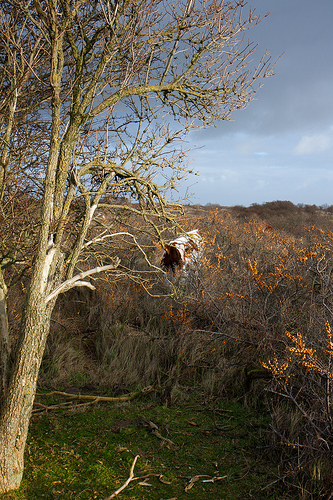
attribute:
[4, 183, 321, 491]
bushes — thick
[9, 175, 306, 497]
bushes — thick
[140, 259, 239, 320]
bushes — thick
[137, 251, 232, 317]
bushes — thick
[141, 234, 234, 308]
bushes — thick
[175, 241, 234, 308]
bushes — thick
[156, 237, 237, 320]
bushes — thick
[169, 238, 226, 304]
bushes — thick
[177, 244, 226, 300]
bushes — thick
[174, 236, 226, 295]
bushes — thick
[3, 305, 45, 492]
bark — brown, green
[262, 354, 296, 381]
leaves — dead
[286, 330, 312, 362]
leaves — orange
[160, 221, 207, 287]
cow — white, brown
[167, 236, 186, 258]
patch — white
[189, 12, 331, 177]
skies — cloudy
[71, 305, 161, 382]
grass — tall, brown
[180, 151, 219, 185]
clouds — white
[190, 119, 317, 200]
sky — blue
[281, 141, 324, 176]
clouds — white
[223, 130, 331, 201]
sky — blue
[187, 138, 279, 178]
sky — blue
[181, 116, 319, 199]
clouds — white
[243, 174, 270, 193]
clouds — white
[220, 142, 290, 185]
sky — blue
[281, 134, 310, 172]
sky — blue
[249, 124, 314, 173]
clouds — white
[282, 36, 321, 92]
clouds — grey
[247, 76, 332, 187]
sky — blue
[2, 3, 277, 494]
tree — with no leaves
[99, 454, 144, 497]
branch — from the tree, on the ground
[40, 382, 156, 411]
branch — on the ground, from the tree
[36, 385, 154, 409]
branch — broken, from the tree, on the ground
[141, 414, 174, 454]
branch — on the ground, from the tree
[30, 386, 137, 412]
branch — from the tree, on the ground